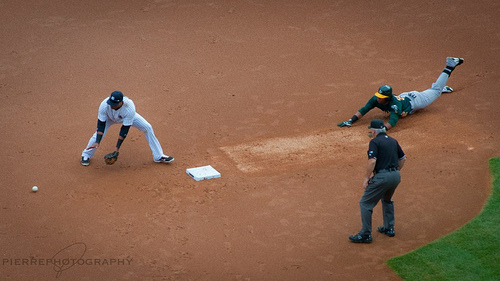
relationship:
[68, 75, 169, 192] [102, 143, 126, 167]
baseball player wearing leather mitt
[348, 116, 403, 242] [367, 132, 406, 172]
umpire with black shirt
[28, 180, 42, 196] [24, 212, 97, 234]
ball on ground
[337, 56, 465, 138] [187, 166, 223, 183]
baseball player sliding into base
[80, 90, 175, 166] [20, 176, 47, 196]
baseball player ready to catch baseball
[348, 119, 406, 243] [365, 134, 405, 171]
umpire wears black shirt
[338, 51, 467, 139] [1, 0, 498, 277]
baseball player diving in dirt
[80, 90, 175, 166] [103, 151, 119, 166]
baseball player has baseball glove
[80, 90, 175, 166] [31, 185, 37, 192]
baseball player catches ball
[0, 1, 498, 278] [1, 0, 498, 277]
field has dirt